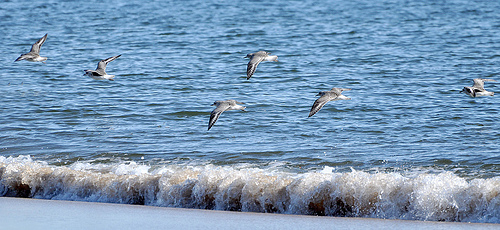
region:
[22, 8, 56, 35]
white clouds in blue sky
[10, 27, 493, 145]
birds flying over water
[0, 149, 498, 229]
long wave in water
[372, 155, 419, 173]
white water splash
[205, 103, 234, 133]
wing of bird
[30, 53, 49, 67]
tail of bird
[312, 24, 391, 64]
dark line ripples in water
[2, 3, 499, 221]
body of water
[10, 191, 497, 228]
sand on shoreline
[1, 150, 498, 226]
white water wave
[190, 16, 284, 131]
dolphins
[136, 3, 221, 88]
ripples in the water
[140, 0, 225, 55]
water in the background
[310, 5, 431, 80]
water in the photo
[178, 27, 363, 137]
three birds in the air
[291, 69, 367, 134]
bird flying above water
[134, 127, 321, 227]
wave in the water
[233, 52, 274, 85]
feather of the bird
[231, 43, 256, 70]
head of the bird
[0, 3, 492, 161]
many light birds in photo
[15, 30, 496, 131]
Birds flying over water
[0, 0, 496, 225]
Ocean (or lake) and beach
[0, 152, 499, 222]
Surf crashing on the beach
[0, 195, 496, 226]
Wet sand at the water's edge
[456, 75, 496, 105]
Bird close to the water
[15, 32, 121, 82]
These birds might soon dive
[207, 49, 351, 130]
Birds gaining speed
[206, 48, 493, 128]
Sharp beaks indicate fishing birds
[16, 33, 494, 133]
Each bird is grey, black, and white